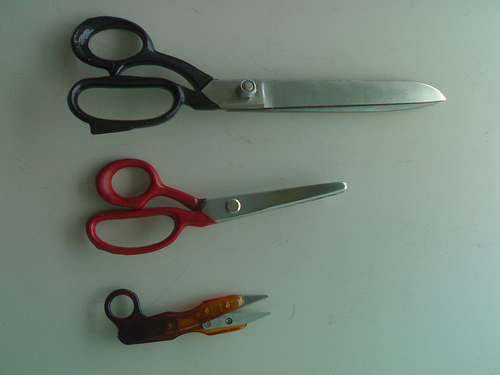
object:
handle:
[94, 157, 200, 211]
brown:
[165, 294, 247, 336]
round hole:
[107, 165, 156, 200]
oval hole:
[93, 215, 181, 249]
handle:
[101, 287, 147, 324]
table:
[3, 5, 498, 373]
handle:
[63, 74, 219, 136]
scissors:
[83, 156, 350, 258]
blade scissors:
[63, 10, 451, 138]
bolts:
[238, 78, 258, 96]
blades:
[201, 76, 447, 110]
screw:
[240, 78, 257, 95]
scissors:
[101, 287, 277, 348]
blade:
[199, 310, 273, 331]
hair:
[288, 306, 297, 321]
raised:
[200, 293, 277, 337]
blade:
[240, 292, 269, 306]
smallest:
[102, 285, 273, 348]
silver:
[244, 180, 347, 219]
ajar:
[198, 291, 274, 337]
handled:
[83, 207, 216, 257]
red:
[79, 156, 217, 259]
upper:
[193, 289, 273, 337]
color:
[172, 295, 247, 337]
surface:
[0, 4, 500, 375]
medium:
[87, 157, 347, 253]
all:
[77, 158, 347, 254]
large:
[66, 14, 446, 134]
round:
[107, 294, 136, 320]